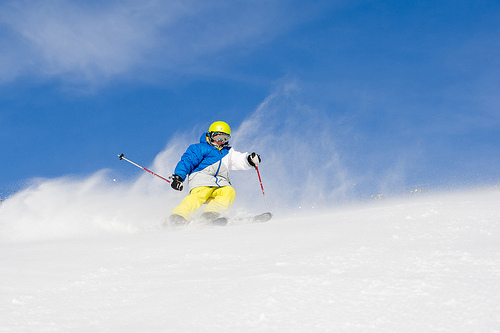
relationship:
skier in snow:
[118, 119, 275, 224] [0, 193, 498, 330]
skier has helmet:
[118, 119, 275, 224] [207, 121, 230, 137]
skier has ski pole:
[118, 119, 275, 224] [118, 152, 172, 186]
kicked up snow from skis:
[1, 164, 160, 230] [116, 152, 280, 225]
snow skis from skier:
[137, 212, 280, 230] [118, 119, 275, 224]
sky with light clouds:
[1, 0, 497, 160] [0, 1, 313, 103]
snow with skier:
[0, 193, 498, 330] [118, 119, 275, 224]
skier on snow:
[118, 119, 275, 224] [0, 193, 498, 330]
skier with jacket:
[118, 119, 275, 224] [174, 141, 251, 189]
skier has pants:
[118, 119, 275, 224] [175, 189, 238, 212]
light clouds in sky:
[0, 1, 313, 103] [1, 0, 497, 160]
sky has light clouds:
[1, 0, 497, 160] [0, 1, 313, 103]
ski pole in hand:
[249, 165, 275, 216] [247, 153, 263, 168]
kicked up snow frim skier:
[1, 164, 160, 230] [118, 119, 275, 224]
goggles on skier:
[209, 134, 231, 144] [118, 119, 275, 224]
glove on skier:
[170, 177, 184, 191] [118, 119, 275, 224]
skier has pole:
[118, 119, 275, 224] [118, 152, 172, 186]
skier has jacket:
[118, 119, 275, 224] [174, 141, 251, 189]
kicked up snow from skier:
[1, 164, 160, 230] [118, 119, 275, 224]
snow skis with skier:
[137, 212, 280, 230] [118, 119, 275, 224]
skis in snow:
[116, 152, 280, 225] [0, 193, 498, 330]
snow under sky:
[0, 193, 498, 330] [1, 0, 497, 160]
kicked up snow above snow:
[1, 164, 160, 230] [0, 193, 498, 330]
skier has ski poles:
[118, 119, 275, 224] [115, 157, 274, 203]